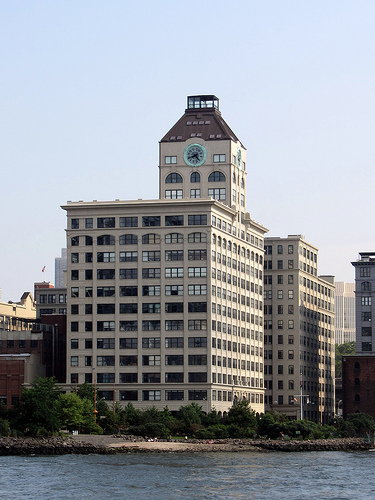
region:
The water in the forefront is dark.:
[114, 460, 150, 498]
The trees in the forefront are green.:
[26, 383, 83, 423]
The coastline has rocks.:
[19, 439, 75, 452]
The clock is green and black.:
[183, 139, 207, 166]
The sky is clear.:
[24, 107, 81, 146]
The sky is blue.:
[18, 96, 80, 143]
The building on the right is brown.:
[346, 359, 369, 414]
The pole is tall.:
[90, 372, 99, 413]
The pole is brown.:
[90, 366, 98, 412]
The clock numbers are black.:
[186, 142, 210, 168]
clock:
[184, 138, 209, 168]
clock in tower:
[178, 138, 206, 165]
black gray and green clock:
[181, 144, 209, 163]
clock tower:
[154, 83, 242, 205]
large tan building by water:
[57, 187, 333, 412]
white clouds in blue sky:
[20, 31, 61, 93]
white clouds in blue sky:
[45, 114, 102, 159]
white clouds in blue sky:
[93, 54, 124, 106]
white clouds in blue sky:
[244, 55, 294, 111]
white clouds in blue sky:
[271, 121, 318, 185]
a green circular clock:
[182, 143, 205, 166]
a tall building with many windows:
[65, 94, 265, 427]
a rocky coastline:
[0, 436, 370, 452]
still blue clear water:
[0, 454, 374, 498]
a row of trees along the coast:
[0, 405, 374, 436]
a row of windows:
[164, 286, 206, 294]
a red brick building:
[0, 334, 48, 404]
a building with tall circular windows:
[356, 251, 373, 354]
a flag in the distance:
[39, 263, 47, 281]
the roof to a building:
[159, 92, 247, 142]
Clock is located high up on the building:
[152, 89, 258, 198]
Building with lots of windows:
[63, 201, 268, 409]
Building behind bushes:
[61, 198, 259, 439]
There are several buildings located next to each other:
[6, 68, 373, 410]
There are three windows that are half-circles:
[155, 81, 253, 201]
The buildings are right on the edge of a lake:
[0, 89, 373, 499]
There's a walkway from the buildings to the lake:
[5, 389, 250, 450]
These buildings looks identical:
[64, 197, 339, 426]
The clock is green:
[155, 90, 247, 197]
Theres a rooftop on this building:
[154, 95, 251, 209]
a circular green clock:
[182, 143, 206, 166]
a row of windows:
[70, 335, 207, 347]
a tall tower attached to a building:
[158, 95, 246, 200]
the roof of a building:
[158, 94, 245, 142]